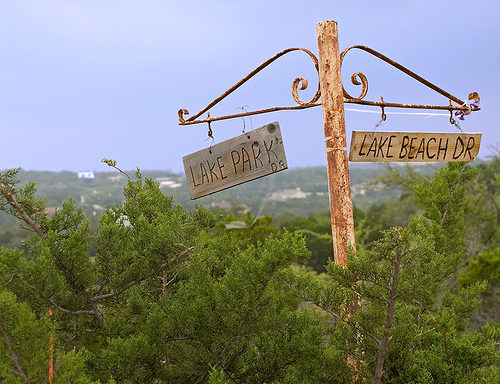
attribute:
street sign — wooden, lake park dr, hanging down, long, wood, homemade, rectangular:
[179, 118, 293, 204]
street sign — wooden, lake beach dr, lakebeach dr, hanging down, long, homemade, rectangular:
[348, 135, 485, 165]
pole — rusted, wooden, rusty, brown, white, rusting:
[317, 20, 360, 268]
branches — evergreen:
[3, 159, 498, 383]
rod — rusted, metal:
[175, 48, 322, 127]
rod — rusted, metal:
[336, 46, 481, 114]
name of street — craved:
[190, 137, 282, 186]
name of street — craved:
[359, 137, 476, 159]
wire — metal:
[207, 111, 250, 140]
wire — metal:
[375, 101, 469, 133]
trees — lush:
[230, 154, 499, 268]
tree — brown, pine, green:
[6, 175, 192, 381]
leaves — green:
[5, 174, 159, 331]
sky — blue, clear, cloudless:
[0, 5, 499, 173]